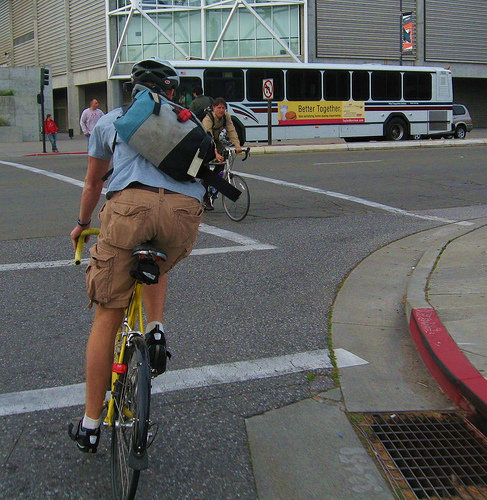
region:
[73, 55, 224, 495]
The man is riding a bike.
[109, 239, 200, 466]
The bike is yellow.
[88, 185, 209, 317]
The man is wearing tan shorts.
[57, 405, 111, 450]
The man has a black shoe.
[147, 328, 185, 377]
The man has a black shoe.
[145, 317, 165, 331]
The man is wearing a white sock.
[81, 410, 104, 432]
The man is wearing a white sock.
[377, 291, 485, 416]
The curb is painted red.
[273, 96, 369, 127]
The bus has a yellow sign.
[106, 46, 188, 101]
The man is wearing a helmet.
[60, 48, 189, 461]
man riding a bike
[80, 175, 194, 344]
the short is brown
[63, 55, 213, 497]
Man riding on a bicycle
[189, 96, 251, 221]
Man crossing the road on a bicycle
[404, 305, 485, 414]
Red paint on a street curb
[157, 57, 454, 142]
White mass transit bus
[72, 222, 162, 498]
Yellow metal frame bicycle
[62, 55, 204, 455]
Man wearing a light blue shirt and cargo shorts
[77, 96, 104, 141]
Man in a sweatshirt crossing the street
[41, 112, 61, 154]
Woman leaning against a light pole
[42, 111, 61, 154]
Woman wearing a red sweatshirt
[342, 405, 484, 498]
Metal road grate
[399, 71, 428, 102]
window on the bus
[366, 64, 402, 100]
window on the bus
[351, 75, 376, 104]
window on the bus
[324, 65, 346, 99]
window on the bus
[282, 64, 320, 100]
window on the bus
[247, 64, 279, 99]
window on the bus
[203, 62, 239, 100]
window on the bus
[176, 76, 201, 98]
window on the bus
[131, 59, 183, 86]
helmet on the rider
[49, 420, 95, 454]
shoe of the rider